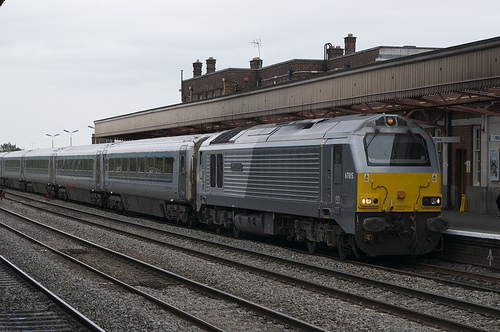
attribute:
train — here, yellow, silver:
[146, 133, 436, 241]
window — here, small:
[361, 129, 435, 172]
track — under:
[291, 254, 424, 308]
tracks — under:
[131, 218, 403, 323]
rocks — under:
[249, 241, 291, 258]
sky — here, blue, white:
[64, 18, 203, 67]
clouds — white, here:
[28, 29, 144, 93]